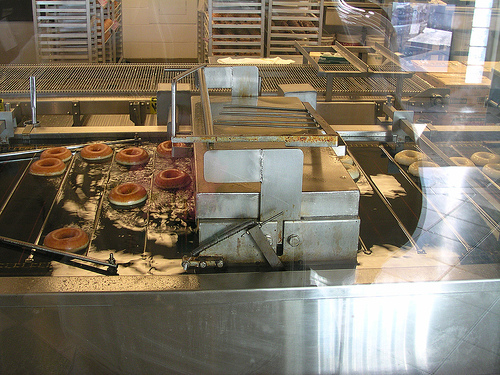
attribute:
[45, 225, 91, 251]
doughnut — fresh, fried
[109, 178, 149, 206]
doughnut — fresh, fried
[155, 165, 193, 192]
doughnut — fresh, fried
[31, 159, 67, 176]
doughnut — fresh, fried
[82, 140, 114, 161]
doughnut — fresh, fried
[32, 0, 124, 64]
bakers rack — empty